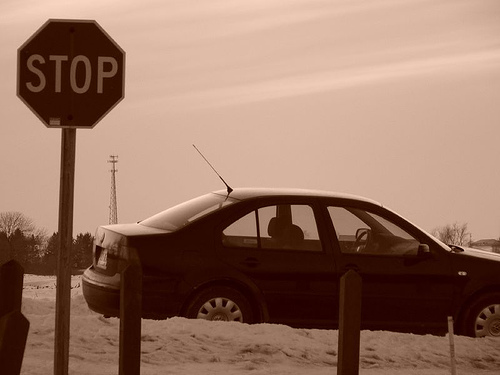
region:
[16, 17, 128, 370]
A stop sign on a pole.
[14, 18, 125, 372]
A sign on a pole.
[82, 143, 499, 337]
A car with an antenna.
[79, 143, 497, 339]
A car in the snow.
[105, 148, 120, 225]
A tower in the background.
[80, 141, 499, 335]
A parked car in the snow.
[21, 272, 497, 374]
Snow on the ground.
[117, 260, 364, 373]
Two woods poles in the snow.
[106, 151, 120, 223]
A power line tower.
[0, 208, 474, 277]
Trees in the background.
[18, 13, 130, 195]
stop sign with the post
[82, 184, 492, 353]
car parked in the snow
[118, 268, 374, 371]
wood fencing in the snow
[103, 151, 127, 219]
electric post in the snow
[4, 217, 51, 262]
plants, trees in the snow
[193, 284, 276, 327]
wheel of the car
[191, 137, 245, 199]
antenna of the car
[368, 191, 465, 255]
front glass with wipers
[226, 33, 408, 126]
sky with clouds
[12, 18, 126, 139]
polygonal sign with the post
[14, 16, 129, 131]
Red and white stop sign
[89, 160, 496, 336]
Small parked car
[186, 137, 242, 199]
Small black antenna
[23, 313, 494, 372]
Deep snow on the ground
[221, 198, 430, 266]
2 clear windows on the car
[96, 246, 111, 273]
License plate on the back of the car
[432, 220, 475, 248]
Small bare tree in the winter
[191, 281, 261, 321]
Black tire on car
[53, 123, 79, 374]
Skinny pole for stop sign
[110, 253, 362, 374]
2 wooden posts.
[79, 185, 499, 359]
a car deep in snow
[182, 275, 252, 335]
the rear wheel of a car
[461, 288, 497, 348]
the front wheel of a car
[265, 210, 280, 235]
the driver's headrest of a car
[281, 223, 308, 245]
the passenger's headrest of a car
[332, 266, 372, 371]
a wooden fencepost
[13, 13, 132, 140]
a red and white stop sign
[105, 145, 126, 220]
a tall metal tower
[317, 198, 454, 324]
the passenger door of a car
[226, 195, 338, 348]
the rear passenger door of a car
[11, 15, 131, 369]
stop sign on pole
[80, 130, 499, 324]
car with rear antenna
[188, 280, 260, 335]
wheel with hub cap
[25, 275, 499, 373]
ground covered with snow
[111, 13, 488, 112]
streaky clouds in sky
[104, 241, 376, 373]
large fence posts on side of road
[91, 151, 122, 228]
large ground antenna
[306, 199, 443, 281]
rear view mirror on passenger side window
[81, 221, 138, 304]
license plate on rear of car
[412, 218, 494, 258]
trees without leaves